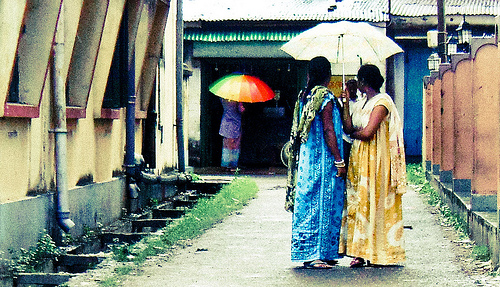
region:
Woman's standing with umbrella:
[244, 0, 432, 283]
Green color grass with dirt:
[170, 210, 238, 278]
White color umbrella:
[271, 10, 411, 66]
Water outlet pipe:
[49, 105, 87, 227]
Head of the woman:
[354, 63, 390, 93]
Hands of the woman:
[320, 111, 382, 181]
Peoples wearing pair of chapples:
[293, 240, 399, 285]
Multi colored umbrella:
[204, 66, 277, 115]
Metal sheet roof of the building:
[227, 3, 351, 18]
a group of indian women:
[296, 42, 420, 274]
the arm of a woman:
[343, 108, 387, 139]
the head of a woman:
[349, 52, 384, 92]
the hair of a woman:
[358, 64, 385, 90]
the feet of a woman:
[345, 250, 370, 265]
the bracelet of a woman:
[333, 156, 349, 170]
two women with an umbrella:
[257, 20, 429, 278]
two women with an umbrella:
[249, 12, 428, 277]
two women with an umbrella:
[262, 20, 416, 275]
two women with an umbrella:
[269, 18, 416, 273]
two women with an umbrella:
[275, 15, 430, 275]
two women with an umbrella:
[255, 15, 411, 272]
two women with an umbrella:
[270, 9, 411, 269]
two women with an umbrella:
[251, 5, 406, 272]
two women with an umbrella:
[278, 23, 420, 283]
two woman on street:
[280, 61, 414, 276]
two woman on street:
[274, 57, 407, 271]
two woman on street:
[278, 55, 408, 279]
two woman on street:
[293, 57, 411, 267]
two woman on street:
[285, 48, 411, 271]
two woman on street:
[286, 50, 416, 272]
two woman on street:
[280, 52, 415, 283]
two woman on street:
[285, 53, 415, 282]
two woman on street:
[284, 59, 407, 273]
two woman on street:
[270, 22, 417, 273]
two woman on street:
[258, 42, 416, 265]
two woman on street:
[272, 50, 409, 278]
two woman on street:
[285, 42, 404, 269]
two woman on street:
[288, 47, 410, 280]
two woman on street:
[272, 48, 406, 271]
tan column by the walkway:
[470, 46, 496, 198]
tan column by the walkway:
[446, 55, 471, 191]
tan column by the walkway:
[441, 63, 453, 176]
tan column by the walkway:
[430, 72, 441, 170]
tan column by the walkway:
[421, 75, 431, 175]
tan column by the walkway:
[105, 1, 140, 106]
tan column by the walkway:
[60, 0, 105, 105]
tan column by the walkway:
[20, 0, 55, 102]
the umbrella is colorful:
[208, 75, 277, 101]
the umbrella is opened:
[207, 74, 276, 103]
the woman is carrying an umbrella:
[208, 74, 276, 172]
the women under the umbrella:
[278, 20, 408, 270]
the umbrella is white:
[278, 19, 404, 106]